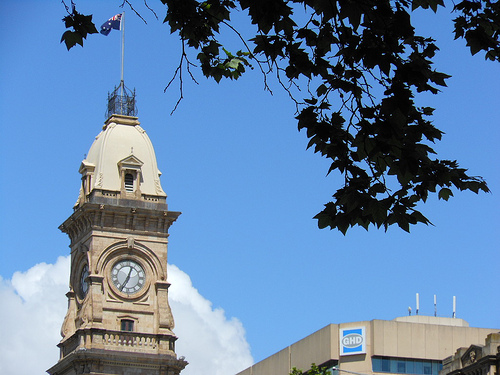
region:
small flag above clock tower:
[95, 11, 129, 38]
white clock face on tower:
[111, 259, 150, 297]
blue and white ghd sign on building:
[337, 329, 372, 355]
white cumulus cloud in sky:
[21, 240, 217, 373]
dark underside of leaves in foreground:
[161, 0, 498, 213]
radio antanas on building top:
[385, 282, 462, 325]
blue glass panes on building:
[362, 351, 451, 373]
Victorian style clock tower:
[63, 75, 205, 372]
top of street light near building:
[330, 359, 382, 374]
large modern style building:
[214, 291, 488, 368]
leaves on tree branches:
[302, 78, 432, 182]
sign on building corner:
[330, 321, 373, 366]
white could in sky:
[195, 316, 228, 358]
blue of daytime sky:
[194, 142, 274, 220]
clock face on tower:
[101, 256, 152, 303]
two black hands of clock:
[115, 262, 138, 299]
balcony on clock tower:
[104, 327, 165, 354]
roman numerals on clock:
[132, 271, 153, 299]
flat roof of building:
[273, 310, 352, 366]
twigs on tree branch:
[162, 55, 201, 114]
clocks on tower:
[75, 256, 147, 301]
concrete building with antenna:
[228, 293, 499, 374]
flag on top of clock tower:
[98, 8, 125, 82]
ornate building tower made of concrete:
[45, 78, 189, 374]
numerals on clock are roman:
[107, 253, 144, 295]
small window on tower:
[121, 153, 146, 199]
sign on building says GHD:
[338, 326, 368, 357]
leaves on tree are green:
[61, 1, 498, 233]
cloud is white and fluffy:
[0, 248, 255, 374]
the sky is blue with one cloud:
[1, 1, 498, 372]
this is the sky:
[218, 136, 295, 267]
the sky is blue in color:
[173, 148, 233, 190]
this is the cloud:
[193, 309, 228, 351]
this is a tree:
[331, 131, 442, 202]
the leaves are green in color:
[379, 129, 442, 175]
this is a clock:
[108, 256, 145, 288]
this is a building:
[374, 323, 494, 372]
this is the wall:
[370, 328, 430, 350]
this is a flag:
[103, 12, 119, 27]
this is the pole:
[121, 23, 126, 78]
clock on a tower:
[92, 243, 159, 296]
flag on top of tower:
[98, 3, 143, 91]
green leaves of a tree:
[279, 72, 469, 262]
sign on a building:
[327, 323, 382, 364]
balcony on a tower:
[69, 326, 194, 361]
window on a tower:
[122, 165, 143, 197]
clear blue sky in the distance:
[205, 113, 287, 275]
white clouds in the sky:
[174, 272, 226, 358]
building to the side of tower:
[232, 291, 497, 373]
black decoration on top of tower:
[105, 83, 140, 124]